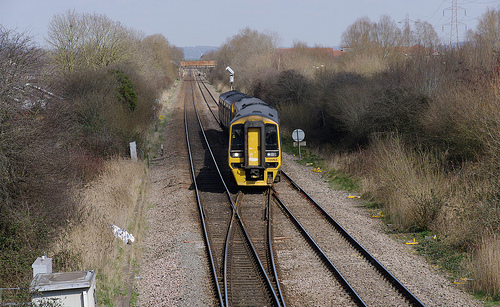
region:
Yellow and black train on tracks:
[221, 73, 291, 208]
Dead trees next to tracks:
[8, 43, 117, 215]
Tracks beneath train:
[197, 195, 329, 292]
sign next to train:
[288, 119, 315, 164]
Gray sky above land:
[167, 6, 322, 48]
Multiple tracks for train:
[190, 207, 372, 291]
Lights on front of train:
[226, 138, 286, 166]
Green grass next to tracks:
[325, 170, 449, 272]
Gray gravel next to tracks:
[146, 202, 191, 297]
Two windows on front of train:
[225, 118, 282, 158]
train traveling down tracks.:
[219, 90, 281, 187]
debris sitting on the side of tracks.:
[109, 222, 135, 244]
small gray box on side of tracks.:
[122, 140, 139, 162]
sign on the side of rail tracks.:
[286, 127, 311, 160]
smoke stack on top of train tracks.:
[221, 66, 241, 91]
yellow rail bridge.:
[177, 59, 217, 69]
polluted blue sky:
[1, 0, 498, 47]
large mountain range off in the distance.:
[3, 46, 498, 56]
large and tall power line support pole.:
[442, 0, 472, 50]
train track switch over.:
[196, 190, 277, 305]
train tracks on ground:
[172, 197, 485, 278]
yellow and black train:
[215, 98, 326, 273]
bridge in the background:
[165, 19, 234, 104]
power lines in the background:
[428, 6, 480, 68]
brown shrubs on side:
[351, 131, 438, 223]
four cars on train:
[172, 79, 339, 259]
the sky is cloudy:
[136, 4, 266, 50]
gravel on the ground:
[168, 211, 279, 286]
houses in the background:
[304, 34, 429, 121]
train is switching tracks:
[200, 78, 319, 252]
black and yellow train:
[210, 85, 287, 200]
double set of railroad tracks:
[196, 212, 288, 298]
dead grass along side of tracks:
[368, 133, 471, 242]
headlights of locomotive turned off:
[227, 147, 280, 164]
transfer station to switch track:
[29, 254, 97, 304]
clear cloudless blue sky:
[157, 6, 272, 33]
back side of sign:
[290, 127, 307, 152]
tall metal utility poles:
[438, 2, 475, 51]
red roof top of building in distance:
[269, 39, 347, 71]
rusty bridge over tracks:
[175, 50, 220, 72]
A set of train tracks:
[176, 121, 228, 213]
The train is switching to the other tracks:
[211, 87, 298, 274]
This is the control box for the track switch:
[22, 247, 110, 302]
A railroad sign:
[289, 123, 314, 168]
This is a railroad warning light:
[224, 60, 242, 91]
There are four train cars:
[212, 87, 287, 199]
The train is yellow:
[229, 123, 283, 186]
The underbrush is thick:
[316, 85, 496, 192]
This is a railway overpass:
[174, 53, 223, 91]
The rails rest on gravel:
[148, 207, 198, 304]